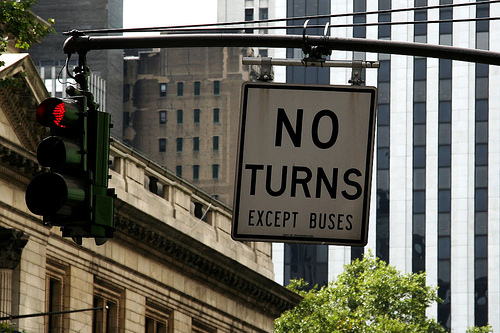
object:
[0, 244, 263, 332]
wall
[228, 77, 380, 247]
sign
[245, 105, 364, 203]
no turns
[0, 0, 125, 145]
building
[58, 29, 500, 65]
pole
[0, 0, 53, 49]
tree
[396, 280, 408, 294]
leaf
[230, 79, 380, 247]
board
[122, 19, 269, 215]
building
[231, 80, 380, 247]
border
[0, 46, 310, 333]
building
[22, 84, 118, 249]
stoplight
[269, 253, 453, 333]
tree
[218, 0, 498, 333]
building